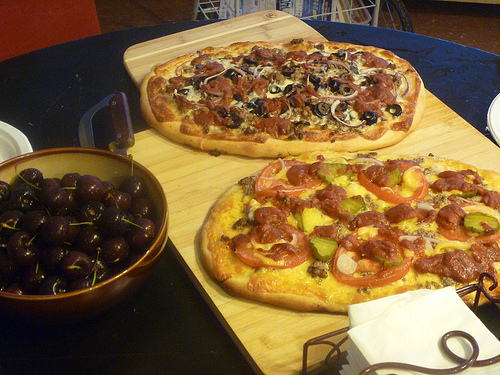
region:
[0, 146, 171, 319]
brown bowl of small red fruit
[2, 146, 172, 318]
brown bowl of cherries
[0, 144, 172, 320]
bowl filled with cherries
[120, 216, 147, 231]
green cherry stem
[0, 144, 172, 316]
bowl of cherries on their stems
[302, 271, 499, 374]
white napkins in a brown holder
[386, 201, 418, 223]
red pizza topping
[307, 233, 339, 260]
pickle topping on a pizza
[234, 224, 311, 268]
slice tomato and red topping on a pizza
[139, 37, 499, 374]
two pizzas on wooden boards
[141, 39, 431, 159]
Large ready combination pizza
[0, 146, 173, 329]
Brown bowl of cherries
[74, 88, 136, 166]
Pizza cutter with brown handle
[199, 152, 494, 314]
Large pizza with tomato slices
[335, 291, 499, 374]
Large stack of white napkins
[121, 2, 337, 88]
Wooden cutting board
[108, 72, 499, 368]
Large yellow cutting board holding two pizzas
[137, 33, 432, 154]
Tasty homemade Italian pizza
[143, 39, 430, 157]
Pizza with olives, onions and meat toppings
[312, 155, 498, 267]
Four pieces of pickles on pizza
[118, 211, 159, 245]
dark red cherry in a bowl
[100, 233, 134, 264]
dark red cherry in a bowl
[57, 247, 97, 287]
dark red cherry in a bowl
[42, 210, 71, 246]
dark red cherry in a bowl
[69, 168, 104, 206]
dark red cherry in a bowl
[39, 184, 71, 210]
dark red cherry in a bowl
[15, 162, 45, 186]
dark red cherry in a bowl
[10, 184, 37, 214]
dark red cherry in a bowl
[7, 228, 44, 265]
dark red cherry in a bowl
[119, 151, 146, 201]
dark red cherry in a bowl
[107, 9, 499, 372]
Wooden tray containing two pizzas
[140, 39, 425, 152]
Pizza with meat, onion and black olives as topping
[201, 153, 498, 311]
Pizza with topping of tomato slices, meat paste, jalapino and cheese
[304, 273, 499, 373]
Metal wire rack holding paper napkins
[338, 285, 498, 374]
Stack of paper napkins in a rack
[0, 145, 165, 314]
Bowl of olives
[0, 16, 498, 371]
Round dark blue table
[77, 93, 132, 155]
Pizza cutter with wooden handle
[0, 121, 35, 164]
Empty white bowl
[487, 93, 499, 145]
Empty white dining plate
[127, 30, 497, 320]
pizza on a table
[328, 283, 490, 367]
napkins in a dispenser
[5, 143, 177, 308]
cherries in a bowl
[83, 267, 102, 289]
stem of a cherry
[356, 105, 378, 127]
olive on a pizza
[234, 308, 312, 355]
wooden table where pizzas are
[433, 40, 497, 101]
blue tablecloth on the table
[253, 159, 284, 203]
tomato on a pizza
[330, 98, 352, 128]
onion on a pizza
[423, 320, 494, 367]
black metal of a dispenser